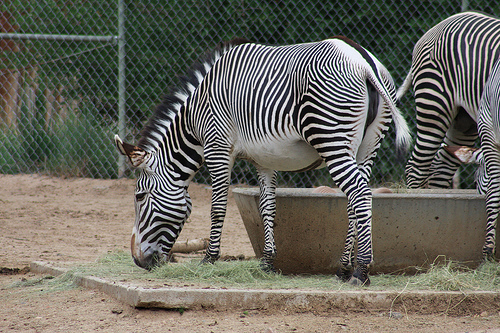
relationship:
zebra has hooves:
[107, 34, 407, 294] [338, 260, 380, 292]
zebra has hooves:
[107, 34, 407, 294] [329, 256, 352, 281]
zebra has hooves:
[107, 34, 407, 294] [252, 252, 269, 276]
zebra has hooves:
[107, 34, 407, 294] [189, 247, 226, 269]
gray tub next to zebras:
[283, 185, 479, 272] [125, 46, 365, 268]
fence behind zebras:
[0, 0, 485, 184] [104, 8, 498, 285]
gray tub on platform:
[234, 185, 499, 273] [29, 248, 496, 318]